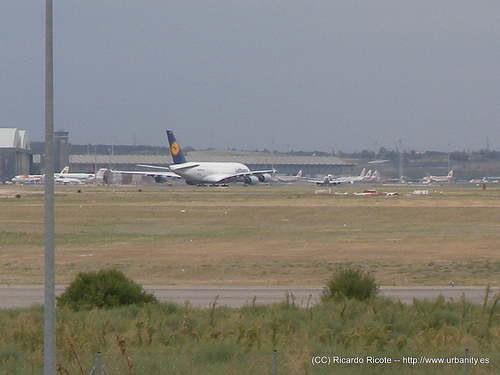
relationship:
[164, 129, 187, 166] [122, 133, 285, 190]
tail attached to airplane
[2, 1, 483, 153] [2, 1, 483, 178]
sky seen in distance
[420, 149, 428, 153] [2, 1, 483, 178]
house standing in distance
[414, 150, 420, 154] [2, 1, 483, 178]
house standing in distance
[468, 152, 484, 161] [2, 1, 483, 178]
house standing in distance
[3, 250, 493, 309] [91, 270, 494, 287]
long tan dirt runway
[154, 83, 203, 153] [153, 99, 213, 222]
airplane tail painted dark blue with yellow circular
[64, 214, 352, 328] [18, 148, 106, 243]
large airport tower with window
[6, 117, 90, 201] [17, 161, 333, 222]
portion of large silver building with roof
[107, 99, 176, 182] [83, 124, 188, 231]
white airplane wing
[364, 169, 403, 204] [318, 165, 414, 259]
large spot painted red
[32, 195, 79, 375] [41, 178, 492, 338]
pole next to airport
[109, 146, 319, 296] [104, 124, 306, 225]
white jumbo jet plane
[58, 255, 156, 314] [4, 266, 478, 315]
bush next to road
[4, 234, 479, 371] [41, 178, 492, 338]
road by airport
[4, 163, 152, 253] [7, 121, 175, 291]
smaller passenger planes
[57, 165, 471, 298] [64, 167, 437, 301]
passenger waiting area and ticket area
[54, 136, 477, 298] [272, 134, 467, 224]
gear for airplanes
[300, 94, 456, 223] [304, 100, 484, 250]
flight radio tower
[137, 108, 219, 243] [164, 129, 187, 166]
navy blue and yellow airplane tail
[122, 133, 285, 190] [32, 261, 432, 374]
airplane landing strip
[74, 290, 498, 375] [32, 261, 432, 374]
bushes along landing strip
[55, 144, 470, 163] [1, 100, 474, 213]
tree line along back of airport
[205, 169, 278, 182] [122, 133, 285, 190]
wing of airplane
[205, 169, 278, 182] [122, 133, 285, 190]
wing on airplane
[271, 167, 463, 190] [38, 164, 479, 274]
planes waiting in field